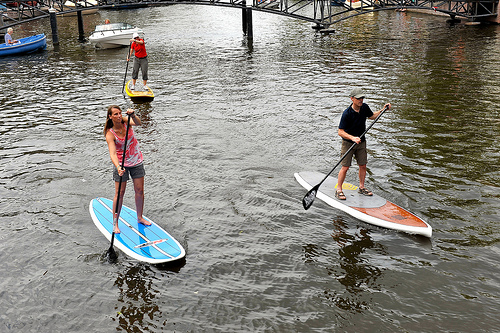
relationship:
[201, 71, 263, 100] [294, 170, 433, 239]
sky sailing with paddle board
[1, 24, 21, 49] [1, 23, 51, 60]
man in blue boat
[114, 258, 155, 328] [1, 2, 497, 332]
reflection in water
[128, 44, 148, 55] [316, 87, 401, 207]
shirt on body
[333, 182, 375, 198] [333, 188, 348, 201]
sandals on foot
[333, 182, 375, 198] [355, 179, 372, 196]
sandals on foot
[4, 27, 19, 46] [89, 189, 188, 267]
man in boat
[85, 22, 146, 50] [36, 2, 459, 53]
boat under bridge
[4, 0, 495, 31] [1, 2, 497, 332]
bridge over water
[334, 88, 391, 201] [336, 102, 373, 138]
body in t-shirt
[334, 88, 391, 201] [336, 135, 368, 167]
body in shorts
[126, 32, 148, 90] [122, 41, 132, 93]
people in oars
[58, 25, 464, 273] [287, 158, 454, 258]
people standing on surfboard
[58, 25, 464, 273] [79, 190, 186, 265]
people standing on surfboard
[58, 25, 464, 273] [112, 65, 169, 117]
people standing on surfboard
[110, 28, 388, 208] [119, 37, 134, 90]
people using oars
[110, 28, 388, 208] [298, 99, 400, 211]
people using oars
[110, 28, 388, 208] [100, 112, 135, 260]
people using oars